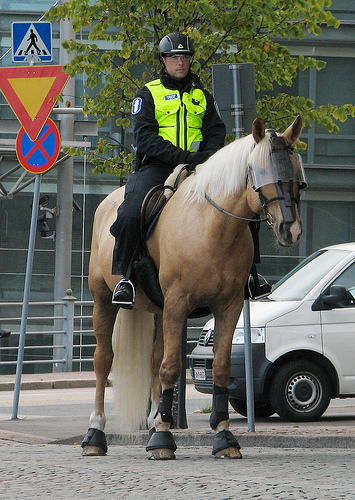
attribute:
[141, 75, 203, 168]
vest — yellow, bright, fluorescent, safety, lime green, neon green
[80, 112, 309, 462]
horse — brown, white, tall, large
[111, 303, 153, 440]
tail — long, beige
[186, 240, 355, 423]
van — white, black, parked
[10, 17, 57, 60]
sign — square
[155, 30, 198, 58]
helmet — black, white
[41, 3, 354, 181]
leaves — green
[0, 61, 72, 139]
sign — red, yellow, yield, triangle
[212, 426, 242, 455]
hoof cover — black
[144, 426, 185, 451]
hoof cover — black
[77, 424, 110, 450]
hoof cover — black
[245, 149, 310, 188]
visor — clear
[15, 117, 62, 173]
sign — circle, blue, red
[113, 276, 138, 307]
stirrup — silver, black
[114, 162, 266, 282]
pants — black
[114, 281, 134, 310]
shoes — dark, black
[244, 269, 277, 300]
shoes — dark, black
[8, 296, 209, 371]
fence — silver, metal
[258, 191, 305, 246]
wraps — black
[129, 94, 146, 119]
patch — blue